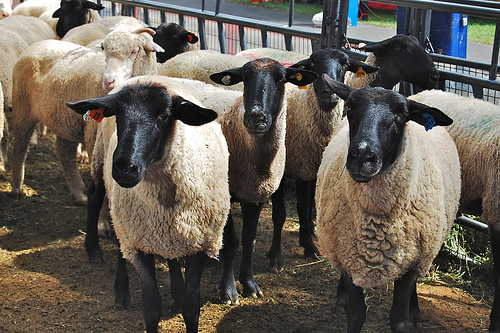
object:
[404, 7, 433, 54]
post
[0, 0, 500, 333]
sheep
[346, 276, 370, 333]
leg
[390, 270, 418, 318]
leg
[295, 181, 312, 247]
leg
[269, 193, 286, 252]
leg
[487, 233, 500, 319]
leg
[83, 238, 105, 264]
hoof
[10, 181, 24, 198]
hoof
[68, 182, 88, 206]
hoof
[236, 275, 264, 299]
hoof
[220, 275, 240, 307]
hoof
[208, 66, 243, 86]
ear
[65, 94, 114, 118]
ear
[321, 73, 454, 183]
head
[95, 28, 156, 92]
heads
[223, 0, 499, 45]
grass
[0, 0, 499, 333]
flock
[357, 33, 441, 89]
herd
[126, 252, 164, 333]
leg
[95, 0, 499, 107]
fence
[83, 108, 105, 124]
tag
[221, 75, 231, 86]
tag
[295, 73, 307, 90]
tag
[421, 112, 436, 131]
tag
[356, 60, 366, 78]
tag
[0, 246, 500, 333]
ground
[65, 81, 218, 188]
head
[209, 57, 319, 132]
head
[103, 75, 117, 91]
snout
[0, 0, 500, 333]
enclosure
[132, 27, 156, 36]
horns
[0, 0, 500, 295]
fur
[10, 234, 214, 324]
shadow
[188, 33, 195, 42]
tag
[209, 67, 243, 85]
ears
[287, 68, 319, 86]
ears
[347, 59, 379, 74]
ears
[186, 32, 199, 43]
ears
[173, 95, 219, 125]
ears